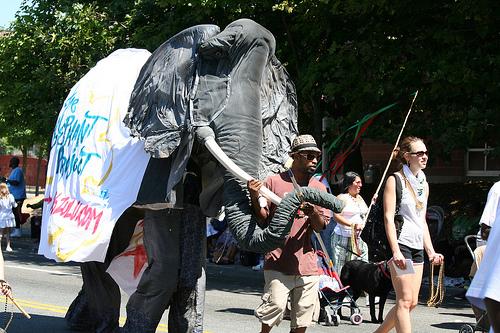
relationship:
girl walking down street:
[359, 135, 447, 333] [213, 280, 253, 322]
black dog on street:
[333, 254, 398, 329] [12, 226, 492, 331]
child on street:
[6, 173, 20, 248] [212, 262, 273, 321]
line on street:
[9, 287, 64, 314] [19, 237, 104, 303]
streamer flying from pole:
[306, 90, 415, 177] [359, 91, 420, 231]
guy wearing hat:
[246, 134, 331, 333] [288, 134, 319, 151]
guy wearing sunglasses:
[246, 134, 331, 333] [303, 150, 320, 157]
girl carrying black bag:
[359, 135, 447, 333] [361, 173, 403, 262]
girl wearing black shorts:
[379, 138, 446, 331] [385, 241, 424, 263]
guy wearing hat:
[251, 127, 331, 321] [291, 132, 330, 154]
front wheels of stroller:
[327, 311, 366, 326] [303, 227, 363, 324]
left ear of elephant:
[256, 65, 296, 175] [36, 18, 345, 331]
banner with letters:
[23, 48, 208, 275] [58, 97, 116, 229]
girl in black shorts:
[359, 135, 447, 333] [380, 236, 427, 267]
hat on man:
[287, 134, 322, 157] [258, 116, 358, 328]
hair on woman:
[333, 163, 364, 200] [332, 165, 379, 324]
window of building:
[464, 147, 489, 174] [318, 115, 498, 257]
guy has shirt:
[246, 134, 331, 333] [266, 151, 352, 247]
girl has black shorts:
[359, 135, 447, 333] [385, 240, 427, 262]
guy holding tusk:
[246, 134, 331, 333] [179, 113, 317, 229]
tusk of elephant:
[179, 113, 317, 229] [105, 30, 384, 274]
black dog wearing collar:
[337, 259, 392, 324] [373, 261, 390, 285]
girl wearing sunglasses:
[359, 135, 447, 333] [410, 149, 428, 158]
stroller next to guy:
[303, 227, 363, 324] [246, 134, 331, 333]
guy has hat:
[246, 134, 331, 333] [288, 134, 323, 155]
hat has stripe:
[288, 134, 323, 155] [290, 143, 317, 149]